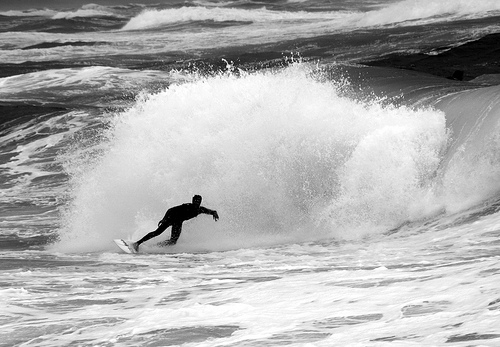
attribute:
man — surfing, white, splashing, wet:
[150, 178, 215, 246]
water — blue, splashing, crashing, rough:
[60, 53, 99, 81]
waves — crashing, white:
[185, 77, 366, 176]